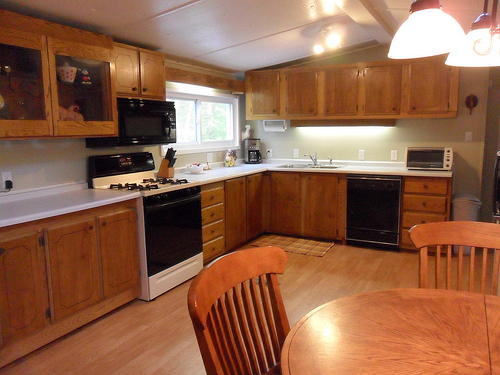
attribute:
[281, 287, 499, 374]
table — wooden, light, wood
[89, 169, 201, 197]
cooktop — black, white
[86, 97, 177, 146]
microwave — black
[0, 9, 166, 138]
cabinets — wooden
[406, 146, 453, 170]
oven — white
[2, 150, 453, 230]
counter — white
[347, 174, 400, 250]
dishwasher — black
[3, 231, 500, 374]
floor — hardwood, wood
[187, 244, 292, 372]
chair — wooden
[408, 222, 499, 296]
chair — wooden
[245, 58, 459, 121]
cabinets — wooden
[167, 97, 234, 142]
window — clear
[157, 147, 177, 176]
knives — set, black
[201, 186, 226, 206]
drawer — light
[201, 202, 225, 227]
drawer — light